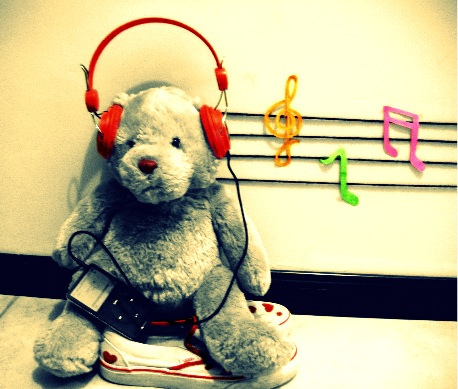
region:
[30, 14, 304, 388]
Gray teddy bear sitting on shoes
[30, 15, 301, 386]
Gray teddy bear wearing red headphones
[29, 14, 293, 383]
Gray teddy bear with red nose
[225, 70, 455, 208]
Music symbols on wall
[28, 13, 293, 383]
Gray teddy bear holding black iPod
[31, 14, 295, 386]
Gray teddy bear listening to music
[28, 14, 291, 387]
Red headphones on a teddy bear's head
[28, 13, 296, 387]
Red nosed teddy bear sitting on white shoes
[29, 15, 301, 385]
Red nosed teddy bear wearing red headphones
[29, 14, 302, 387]
Red nosed teddy bear with black iPod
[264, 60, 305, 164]
Orange music note on wall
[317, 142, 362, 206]
green music note on wall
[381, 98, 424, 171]
purple music note on wall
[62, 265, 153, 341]
black and grey ipod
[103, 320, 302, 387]
red and white shoe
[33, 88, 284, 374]
Grey teddy bear with head phones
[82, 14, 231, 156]
Bright read over the ear head phones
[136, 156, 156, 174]
Red nose of teddy bear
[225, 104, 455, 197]
Black lines on the wall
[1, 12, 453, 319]
Tan and black wall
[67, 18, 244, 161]
red headphones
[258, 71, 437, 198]
music notes on the wall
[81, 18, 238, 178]
stuffed animal is wearing headphones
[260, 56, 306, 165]
orange music note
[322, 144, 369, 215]
green music note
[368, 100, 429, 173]
pink music not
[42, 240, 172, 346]
music playing in the headphones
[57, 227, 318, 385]
animal seating on shoes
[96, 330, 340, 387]
shoes are red and white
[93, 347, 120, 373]
heart on the back of shoe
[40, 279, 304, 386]
teddy bear kept over shoes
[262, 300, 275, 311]
small red heart on shoe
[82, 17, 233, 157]
red head phone over ear of soft toy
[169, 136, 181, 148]
Black eyes of soft toy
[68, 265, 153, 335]
black color apple i pod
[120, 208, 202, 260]
smooth furry teddy bear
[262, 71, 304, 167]
musical cord mentioned on wall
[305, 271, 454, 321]
black border at bottom of wall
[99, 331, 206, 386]
white shoe with red stripe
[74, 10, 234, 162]
vibrant red head phones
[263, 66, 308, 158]
Orange wall mounted musical note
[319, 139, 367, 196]
Green note mounted on the wall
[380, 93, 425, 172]
Purple musical note mounted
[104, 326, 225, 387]
Red and white shoes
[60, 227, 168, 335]
Black and grey ipod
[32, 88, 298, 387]
Teddy bear wearing red headphones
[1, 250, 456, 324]
Black band on wall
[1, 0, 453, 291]
Beige wall behind teddy bear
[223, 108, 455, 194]
Black lines on wall